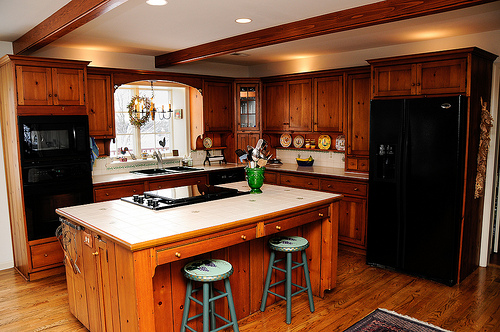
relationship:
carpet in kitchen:
[312, 299, 477, 329] [0, 5, 498, 329]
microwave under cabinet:
[19, 110, 95, 162] [10, 58, 83, 108]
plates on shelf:
[272, 129, 346, 154] [250, 119, 356, 183]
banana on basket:
[294, 156, 308, 161] [295, 158, 315, 166]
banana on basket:
[306, 154, 313, 161] [295, 158, 315, 166]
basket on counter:
[295, 158, 315, 166] [250, 160, 367, 180]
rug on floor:
[338, 305, 455, 329] [2, 236, 498, 328]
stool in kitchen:
[269, 240, 314, 303] [259, 230, 315, 322]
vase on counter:
[246, 165, 265, 194] [56, 179, 340, 249]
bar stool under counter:
[179, 256, 238, 332] [56, 179, 340, 249]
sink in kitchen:
[125, 148, 195, 174] [3, 0, 371, 260]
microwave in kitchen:
[19, 110, 95, 162] [4, 7, 457, 297]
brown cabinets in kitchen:
[268, 77, 371, 124] [25, 11, 330, 296]